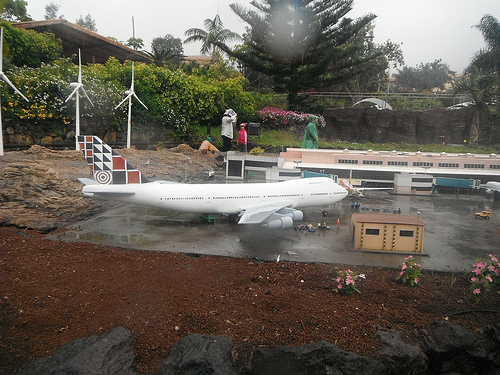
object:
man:
[220, 109, 237, 153]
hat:
[223, 108, 233, 115]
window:
[268, 195, 275, 198]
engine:
[261, 216, 294, 230]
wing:
[238, 201, 293, 224]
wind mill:
[115, 60, 149, 148]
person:
[236, 123, 247, 153]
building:
[343, 212, 431, 255]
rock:
[291, 268, 316, 288]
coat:
[221, 115, 238, 139]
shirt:
[237, 129, 248, 144]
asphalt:
[143, 214, 245, 246]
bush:
[142, 68, 263, 142]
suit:
[302, 114, 320, 149]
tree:
[231, 0, 407, 111]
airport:
[42, 148, 500, 272]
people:
[301, 114, 320, 148]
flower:
[332, 261, 362, 297]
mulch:
[95, 290, 446, 362]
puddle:
[431, 211, 496, 266]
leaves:
[224, 22, 298, 80]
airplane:
[74, 134, 348, 229]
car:
[474, 211, 491, 219]